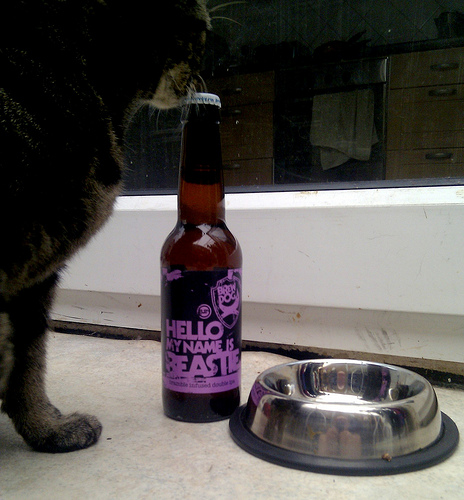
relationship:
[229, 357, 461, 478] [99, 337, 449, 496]
cat dish on ground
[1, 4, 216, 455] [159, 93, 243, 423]
cat standing by beer bottle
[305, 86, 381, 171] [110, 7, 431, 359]
towel reflection in window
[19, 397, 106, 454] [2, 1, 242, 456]
paw on cat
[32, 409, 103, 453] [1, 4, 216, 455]
paw on cat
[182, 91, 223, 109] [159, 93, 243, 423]
cap on beer bottle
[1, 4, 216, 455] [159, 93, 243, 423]
cat sniffing beer bottle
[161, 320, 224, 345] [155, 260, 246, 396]
word on label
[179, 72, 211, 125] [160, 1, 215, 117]
whiskers on face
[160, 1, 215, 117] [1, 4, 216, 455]
face on cat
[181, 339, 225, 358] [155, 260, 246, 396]
name on label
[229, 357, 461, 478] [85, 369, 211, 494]
cat dish on floor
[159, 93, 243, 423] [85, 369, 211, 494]
beer bottle on floor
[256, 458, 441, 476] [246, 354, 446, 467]
rim around dish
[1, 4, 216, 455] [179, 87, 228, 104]
cat sniffing cap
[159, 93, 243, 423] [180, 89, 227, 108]
beer bottle with cap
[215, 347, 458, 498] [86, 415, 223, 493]
cat dish on floor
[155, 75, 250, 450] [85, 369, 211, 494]
beer bottle on floor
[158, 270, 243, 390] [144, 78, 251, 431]
label on bottle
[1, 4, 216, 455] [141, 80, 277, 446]
cat beside bottle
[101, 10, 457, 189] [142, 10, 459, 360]
pane in door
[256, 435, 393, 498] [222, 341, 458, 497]
rim on dish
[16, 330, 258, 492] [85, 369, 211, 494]
carpeting on floor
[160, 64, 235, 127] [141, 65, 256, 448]
cap on bottle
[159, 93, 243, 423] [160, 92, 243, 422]
beer bottle of beer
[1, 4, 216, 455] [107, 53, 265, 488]
cat sniffing bottle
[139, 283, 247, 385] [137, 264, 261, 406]
label on bottle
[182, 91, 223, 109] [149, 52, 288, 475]
cap on bottle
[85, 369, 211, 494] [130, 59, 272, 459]
floor under bottle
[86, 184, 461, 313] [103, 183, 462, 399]
baseboard of wall